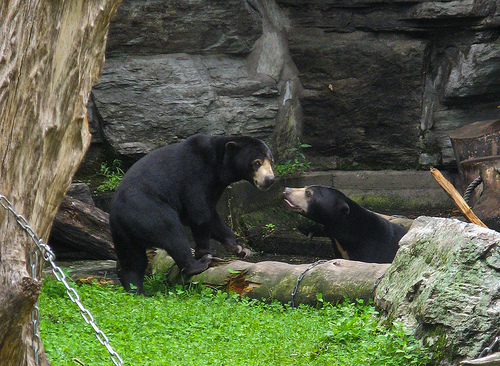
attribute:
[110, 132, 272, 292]
bear — black, standing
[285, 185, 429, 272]
bear — black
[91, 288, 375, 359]
foliage — green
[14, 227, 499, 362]
ground — green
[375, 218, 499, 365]
boulder — large, gray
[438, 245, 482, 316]
moss — green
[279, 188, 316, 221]
mouth — open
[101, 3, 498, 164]
wall — boulders, stone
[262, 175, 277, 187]
nose — black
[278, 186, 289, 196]
nose — black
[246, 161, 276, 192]
snout — brown